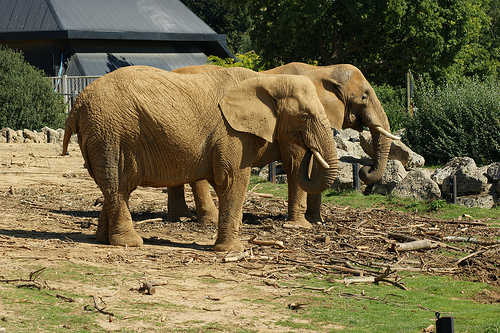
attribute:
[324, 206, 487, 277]
branches — brown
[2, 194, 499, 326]
ground — brown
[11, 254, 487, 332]
grass — green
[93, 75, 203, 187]
skin — elephant's, wrinkled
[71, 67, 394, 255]
elephants — large, huge, big, brown, together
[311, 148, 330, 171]
tusks — ivory, elephant's, large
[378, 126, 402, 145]
tusks — ivory, elephant's, white, large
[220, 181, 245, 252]
leg — elephant's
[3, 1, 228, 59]
roof — grey, slanted, building's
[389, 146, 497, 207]
rocks — rough, grey, large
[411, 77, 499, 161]
bush — green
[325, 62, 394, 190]
elephant — large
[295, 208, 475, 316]
wood — broken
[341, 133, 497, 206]
pile — large, rocks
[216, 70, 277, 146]
ear — elephant's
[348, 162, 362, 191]
post — wooden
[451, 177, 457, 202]
post — wooden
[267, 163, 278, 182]
post — wooden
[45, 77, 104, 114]
fence — wooden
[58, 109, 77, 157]
tail — elephant's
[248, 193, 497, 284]
sticks — dry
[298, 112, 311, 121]
eye — elephant's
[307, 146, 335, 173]
tusk — elephant's, white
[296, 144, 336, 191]
trunk — elephant's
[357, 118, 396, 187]
trunk — elephant's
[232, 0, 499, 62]
trees — green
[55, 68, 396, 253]
elephtants — brown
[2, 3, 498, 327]
day — clear, bright, sunny